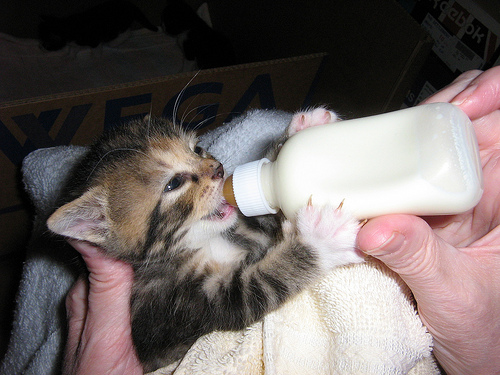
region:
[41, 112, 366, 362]
Kitten in person's hands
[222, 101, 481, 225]
Nursing bottle filled with milk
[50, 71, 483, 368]
Kitten nursing from a bottle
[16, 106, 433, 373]
Blanket wrapped around kitten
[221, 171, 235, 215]
Nipple on nursing bottle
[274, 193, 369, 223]
Extended claws on kitten's paw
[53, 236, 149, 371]
Hand cradling a kitten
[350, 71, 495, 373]
Hand holding a nursing bottle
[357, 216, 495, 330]
Right thumb of a person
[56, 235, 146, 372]
Hand caressing a kitten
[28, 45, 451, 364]
this a kitten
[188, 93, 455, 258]
this is a bottle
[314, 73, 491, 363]
this is a hand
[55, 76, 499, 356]
a kitten drinking a bottle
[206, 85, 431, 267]
kitten is holding the bottle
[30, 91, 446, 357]
kitten is wrapped in a towel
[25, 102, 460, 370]
the towel is white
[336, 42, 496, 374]
hand holding a bottle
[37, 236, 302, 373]
grey leg of kitten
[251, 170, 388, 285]
white paw on kitten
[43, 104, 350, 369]
Kitten in a towel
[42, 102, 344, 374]
Kitten is in a towel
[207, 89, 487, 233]
Kitten holding a bottle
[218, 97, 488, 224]
Kitten is holding a bottle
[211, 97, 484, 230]
Bottle filled with kitten milk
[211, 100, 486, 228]
Bottle is filled with kitten milk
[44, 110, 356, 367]
Kitten being fed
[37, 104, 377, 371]
Kitten is being fed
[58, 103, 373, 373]
Kitten being bottle fed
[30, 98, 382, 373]
Kitten is being bottle fed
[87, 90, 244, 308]
the head of a cat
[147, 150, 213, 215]
the eye of a cat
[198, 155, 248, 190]
the nose of a cat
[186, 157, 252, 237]
the mouth of a cat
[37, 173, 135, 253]
the ear of a cat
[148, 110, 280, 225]
the whiskers of a cat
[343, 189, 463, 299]
the thumb of a cat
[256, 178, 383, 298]
the paw of a cat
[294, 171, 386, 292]
the claws of a cat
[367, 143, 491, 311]
the hand of a man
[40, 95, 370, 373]
baby kitten nursing from a bottle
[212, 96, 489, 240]
small bottle for nursing kittens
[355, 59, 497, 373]
person's right hand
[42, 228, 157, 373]
person's left hand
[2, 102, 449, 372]
small white terricloth towel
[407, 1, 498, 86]
black and white reebok box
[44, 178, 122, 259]
little fuzzy kitten ear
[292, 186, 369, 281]
little fuzzy white kitten paw